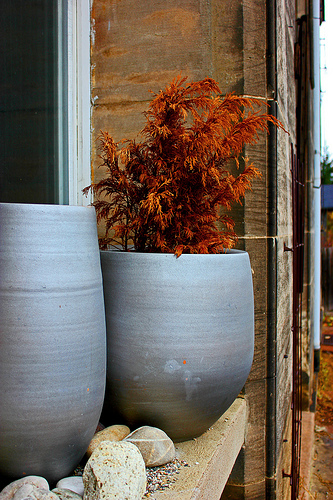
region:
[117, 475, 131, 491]
part of a stone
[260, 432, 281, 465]
part of a pipe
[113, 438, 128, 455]
part of a stone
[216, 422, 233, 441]
part of an edge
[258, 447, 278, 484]
edge of a pipe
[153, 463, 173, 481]
part of a stand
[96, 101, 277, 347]
The plant is in the pot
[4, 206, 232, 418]
Two grey planters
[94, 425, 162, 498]
Three rocks next to each other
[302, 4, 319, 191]
A metal pipe hangs from building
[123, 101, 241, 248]
The plant is orange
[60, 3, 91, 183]
The window is white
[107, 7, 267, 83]
The siding is wooden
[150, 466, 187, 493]
Multicolored granules on the ledge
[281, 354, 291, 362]
A nail in the siding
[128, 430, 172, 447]
A scratch on the rock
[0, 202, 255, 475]
Two large planters seated together.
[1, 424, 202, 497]
Stones on a wooden shelf.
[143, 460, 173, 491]
Pebbles on the wooden shelf.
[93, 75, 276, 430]
An orange colored plant in a pot.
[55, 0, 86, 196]
A white door frame.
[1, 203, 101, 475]
An empty planter.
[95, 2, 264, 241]
A wooden wall behind the plant.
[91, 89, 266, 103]
A seam in the wooden wall.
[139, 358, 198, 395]
Spots on the planter.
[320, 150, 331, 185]
The edge of a tree.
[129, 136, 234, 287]
tree in a planter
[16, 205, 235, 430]
two planters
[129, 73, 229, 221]
tree is reddish color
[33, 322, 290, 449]
planters are on a wooden shelf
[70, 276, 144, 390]
planters is grey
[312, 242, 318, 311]
white pipe attached to house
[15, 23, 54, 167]
window in front of planters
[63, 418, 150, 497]
rocks in front of planters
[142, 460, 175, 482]
pebbles next to rocks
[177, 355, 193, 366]
paint spot on the planter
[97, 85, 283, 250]
an orange potted plant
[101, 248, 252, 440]
a squat silver planter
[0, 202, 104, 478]
a tall empty planter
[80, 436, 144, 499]
a porous rock sitting on a shelf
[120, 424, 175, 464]
a rock with white veins on a shelf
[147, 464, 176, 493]
granular sand like rocks on a shelf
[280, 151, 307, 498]
a rusty grate on a wall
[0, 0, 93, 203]
a window on a wall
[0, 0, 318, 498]
a tan house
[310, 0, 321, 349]
a long silver pipe on a wall